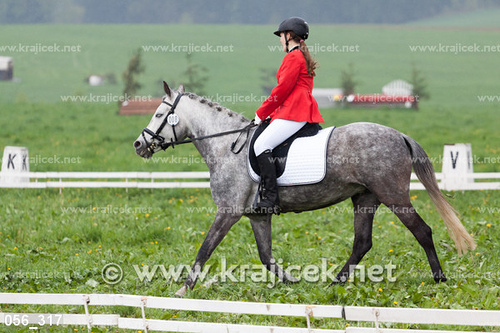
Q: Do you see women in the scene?
A: Yes, there is a woman.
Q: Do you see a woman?
A: Yes, there is a woman.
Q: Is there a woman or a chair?
A: Yes, there is a woman.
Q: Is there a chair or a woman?
A: Yes, there is a woman.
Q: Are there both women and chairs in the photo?
A: No, there is a woman but no chairs.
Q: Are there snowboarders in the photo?
A: No, there are no snowboarders.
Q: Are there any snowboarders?
A: No, there are no snowboarders.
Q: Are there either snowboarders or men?
A: No, there are no snowboarders or men.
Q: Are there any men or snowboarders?
A: No, there are no snowboarders or men.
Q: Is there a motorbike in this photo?
A: No, there are no motorcycles.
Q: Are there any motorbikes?
A: No, there are no motorbikes.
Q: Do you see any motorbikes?
A: No, there are no motorbikes.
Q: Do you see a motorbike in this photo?
A: No, there are no motorcycles.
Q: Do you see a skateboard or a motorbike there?
A: No, there are no motorcycles or skateboards.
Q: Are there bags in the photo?
A: No, there are no bags.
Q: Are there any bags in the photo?
A: No, there are no bags.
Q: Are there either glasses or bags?
A: No, there are no bags or glasses.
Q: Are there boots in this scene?
A: Yes, there are boots.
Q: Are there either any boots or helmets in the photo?
A: Yes, there are boots.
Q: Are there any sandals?
A: No, there are no sandals.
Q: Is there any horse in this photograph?
A: Yes, there is a horse.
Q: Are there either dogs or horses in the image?
A: Yes, there is a horse.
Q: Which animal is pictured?
A: The animal is a horse.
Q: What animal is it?
A: The animal is a horse.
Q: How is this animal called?
A: This is a horse.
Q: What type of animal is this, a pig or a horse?
A: This is a horse.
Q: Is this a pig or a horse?
A: This is a horse.